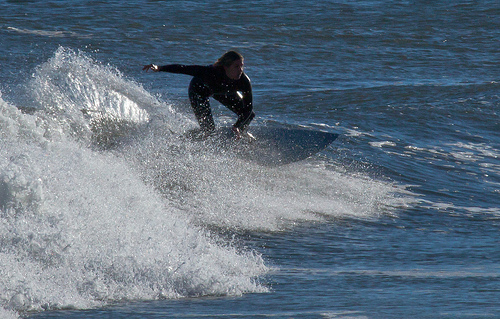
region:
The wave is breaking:
[19, 55, 449, 298]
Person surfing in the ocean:
[142, 27, 367, 180]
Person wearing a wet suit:
[132, 32, 281, 149]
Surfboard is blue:
[169, 105, 377, 180]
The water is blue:
[19, 9, 496, 312]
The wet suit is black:
[135, 62, 280, 150]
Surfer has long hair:
[188, 47, 255, 69]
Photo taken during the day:
[4, 10, 495, 315]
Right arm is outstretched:
[110, 45, 222, 86]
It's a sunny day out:
[0, 0, 492, 314]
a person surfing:
[141, 29, 366, 193]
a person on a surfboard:
[115, 35, 365, 196]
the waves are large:
[2, 46, 372, 302]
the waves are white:
[8, 55, 396, 307]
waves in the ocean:
[5, 51, 366, 316]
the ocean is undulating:
[7, 1, 497, 298]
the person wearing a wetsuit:
[130, 45, 280, 145]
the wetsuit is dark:
[150, 55, 280, 150]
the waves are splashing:
[7, 43, 333, 220]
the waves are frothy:
[3, 51, 415, 306]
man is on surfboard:
[158, 34, 265, 133]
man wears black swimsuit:
[139, 39, 259, 142]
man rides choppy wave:
[0, 113, 244, 315]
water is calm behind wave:
[133, 3, 465, 70]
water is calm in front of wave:
[283, 226, 495, 303]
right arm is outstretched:
[145, 51, 241, 106]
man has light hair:
[208, 31, 241, 75]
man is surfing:
[169, 31, 266, 179]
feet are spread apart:
[157, 120, 262, 156]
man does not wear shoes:
[148, 54, 264, 150]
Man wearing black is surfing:
[153, 46, 275, 141]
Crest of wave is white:
[35, 77, 360, 276]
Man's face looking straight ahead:
[221, 45, 249, 84]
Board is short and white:
[171, 132, 355, 155]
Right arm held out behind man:
[136, 56, 197, 79]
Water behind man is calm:
[255, 11, 495, 69]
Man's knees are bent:
[193, 112, 272, 124]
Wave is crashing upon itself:
[34, 47, 162, 136]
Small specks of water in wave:
[149, 150, 179, 167]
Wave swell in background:
[341, 77, 491, 112]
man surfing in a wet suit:
[2, 10, 483, 287]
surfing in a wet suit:
[134, 50, 351, 170]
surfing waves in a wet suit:
[5, 41, 485, 292]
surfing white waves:
[4, 30, 458, 282]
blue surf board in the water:
[162, 118, 346, 166]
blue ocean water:
[367, 24, 495, 291]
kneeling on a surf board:
[91, 42, 349, 174]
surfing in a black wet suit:
[117, 42, 352, 166]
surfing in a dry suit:
[111, 32, 399, 173]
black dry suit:
[100, 47, 390, 192]